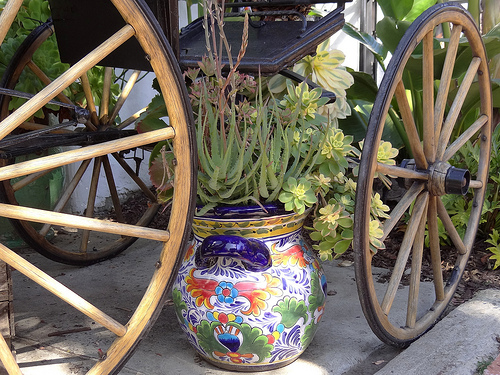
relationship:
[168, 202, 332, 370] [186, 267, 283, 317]
pot has flower decorations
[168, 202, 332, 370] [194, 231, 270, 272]
pot has handle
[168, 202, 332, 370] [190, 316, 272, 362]
pot has flower decorations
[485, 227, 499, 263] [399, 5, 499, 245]
leaves in garden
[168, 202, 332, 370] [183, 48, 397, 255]
pot has plant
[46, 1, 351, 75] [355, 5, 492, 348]
cart has wheel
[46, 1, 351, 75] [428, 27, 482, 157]
cart has spokes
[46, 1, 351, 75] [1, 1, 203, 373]
cart has wheel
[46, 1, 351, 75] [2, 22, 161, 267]
cart has wheel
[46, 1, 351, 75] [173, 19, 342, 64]
cart has seat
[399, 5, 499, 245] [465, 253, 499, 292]
garden has mulch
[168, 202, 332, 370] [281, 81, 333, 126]
pot has flower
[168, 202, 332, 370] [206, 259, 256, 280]
pot has flower decorations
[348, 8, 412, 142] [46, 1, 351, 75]
leaves behind cart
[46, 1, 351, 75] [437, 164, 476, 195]
cart has knob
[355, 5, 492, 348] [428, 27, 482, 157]
wheel has spokes